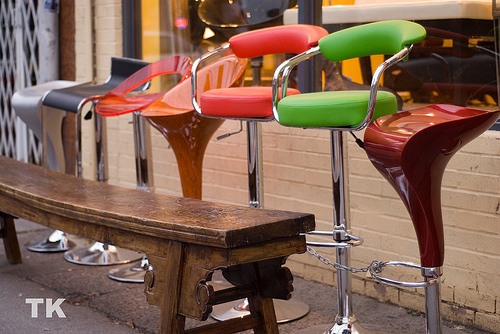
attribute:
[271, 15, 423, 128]
chair — green, chained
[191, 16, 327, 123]
chair — red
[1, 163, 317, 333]
bench — wood, long, carved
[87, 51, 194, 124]
chair — orange, tall, lucite/acrylic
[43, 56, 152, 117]
chair — black, chrome, curved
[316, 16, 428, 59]
back cushion — green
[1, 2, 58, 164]
gate — white, folding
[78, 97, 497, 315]
wall — brick, beige, painted, storefront, dirty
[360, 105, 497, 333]
stool — backless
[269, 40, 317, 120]
arm rests — chrome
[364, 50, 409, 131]
arm rests — chrome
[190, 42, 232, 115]
arm rest — chrome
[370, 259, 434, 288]
foot rest — chrome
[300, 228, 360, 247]
foot rest — chrome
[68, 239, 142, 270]
base — round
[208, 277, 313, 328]
base — round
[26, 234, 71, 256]
base — round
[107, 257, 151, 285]
base — round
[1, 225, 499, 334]
sidewalk — concrete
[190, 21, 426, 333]
chairs — the same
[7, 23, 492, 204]
chairs — muticolored